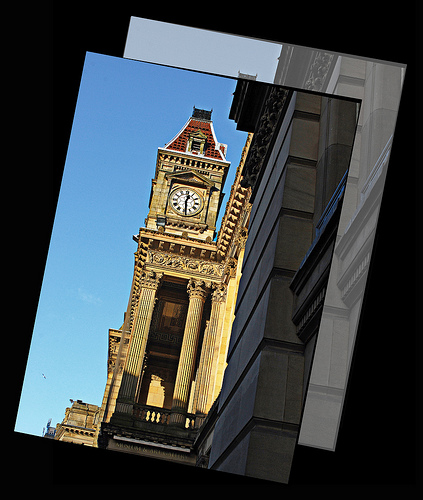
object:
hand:
[185, 194, 191, 214]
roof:
[163, 120, 222, 165]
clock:
[170, 186, 205, 217]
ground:
[304, 175, 325, 209]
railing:
[115, 395, 213, 445]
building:
[0, 0, 423, 500]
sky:
[12, 49, 246, 447]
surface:
[192, 274, 234, 414]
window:
[191, 139, 202, 154]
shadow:
[104, 365, 207, 453]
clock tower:
[89, 104, 233, 468]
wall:
[229, 248, 269, 442]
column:
[109, 267, 163, 428]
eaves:
[226, 72, 279, 135]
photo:
[0, 0, 423, 500]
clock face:
[173, 189, 201, 216]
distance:
[23, 360, 101, 456]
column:
[167, 277, 208, 429]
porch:
[105, 404, 201, 447]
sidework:
[133, 244, 219, 281]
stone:
[208, 85, 333, 485]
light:
[198, 288, 238, 412]